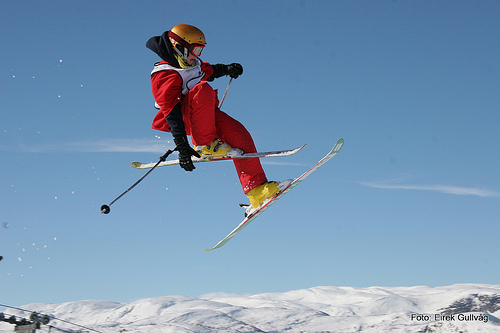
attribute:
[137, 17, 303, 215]
skier — crying out, skiing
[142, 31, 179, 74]
hoody — black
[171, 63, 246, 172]
gloves — black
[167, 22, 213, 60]
helmet — gold, yellow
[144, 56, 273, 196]
jump suit — red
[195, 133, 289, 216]
boots — yellow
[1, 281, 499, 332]
mountains — snow capped, white, snow-capped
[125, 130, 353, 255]
skis — white,green and red, white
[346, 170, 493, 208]
clouds — few, white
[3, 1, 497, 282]
sky — blue